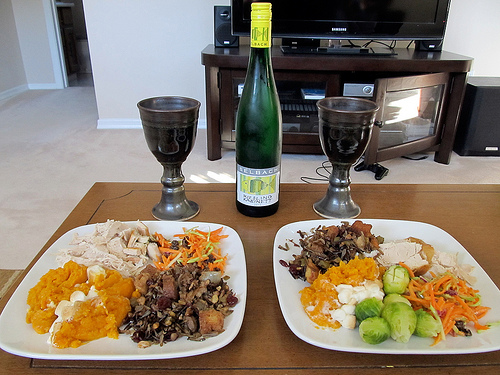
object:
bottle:
[235, 3, 283, 217]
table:
[0, 181, 499, 374]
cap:
[249, 3, 273, 50]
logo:
[331, 26, 349, 32]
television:
[231, 1, 452, 53]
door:
[364, 73, 450, 165]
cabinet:
[201, 44, 473, 165]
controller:
[353, 159, 390, 181]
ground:
[0, 90, 499, 271]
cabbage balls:
[358, 315, 391, 343]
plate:
[272, 218, 499, 354]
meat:
[57, 220, 157, 278]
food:
[32, 216, 241, 350]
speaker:
[452, 75, 500, 155]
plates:
[0, 220, 248, 361]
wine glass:
[137, 97, 201, 222]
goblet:
[314, 96, 377, 219]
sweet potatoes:
[300, 256, 377, 325]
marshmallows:
[339, 315, 356, 330]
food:
[278, 218, 495, 344]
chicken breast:
[380, 235, 476, 283]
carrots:
[435, 302, 473, 324]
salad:
[409, 271, 487, 333]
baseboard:
[96, 118, 206, 130]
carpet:
[0, 89, 499, 267]